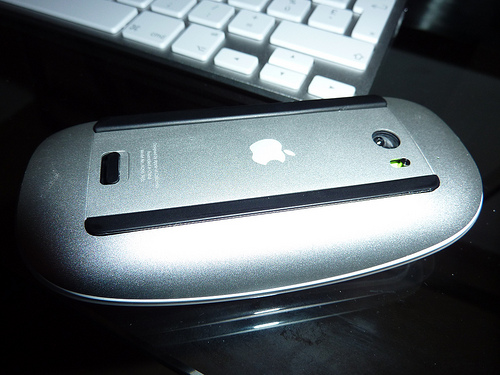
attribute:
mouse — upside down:
[11, 87, 491, 348]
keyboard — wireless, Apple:
[29, 0, 410, 122]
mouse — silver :
[26, 116, 488, 304]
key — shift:
[277, 22, 348, 74]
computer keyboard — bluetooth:
[0, 2, 410, 100]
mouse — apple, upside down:
[19, 93, 486, 308]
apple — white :
[244, 132, 294, 167]